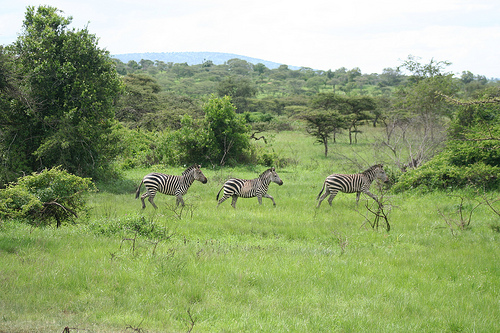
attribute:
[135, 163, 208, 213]
zebra — running, young, standing, playing, striped, white, black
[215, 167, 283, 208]
zebra — large, traveling, black, white, walking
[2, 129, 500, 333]
grass — field, open, tall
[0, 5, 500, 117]
forest — mountainous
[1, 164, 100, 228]
bush — green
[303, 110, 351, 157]
tree — green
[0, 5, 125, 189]
tree — tall, green